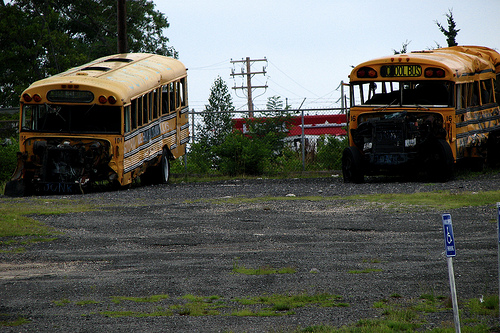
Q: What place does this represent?
A: It represents the road.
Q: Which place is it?
A: It is a road.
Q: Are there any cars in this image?
A: No, there are no cars.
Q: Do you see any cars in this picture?
A: No, there are no cars.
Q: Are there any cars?
A: No, there are no cars.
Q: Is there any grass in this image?
A: Yes, there is grass.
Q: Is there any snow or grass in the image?
A: Yes, there is grass.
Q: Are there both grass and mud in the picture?
A: No, there is grass but no mud.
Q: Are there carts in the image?
A: No, there are no carts.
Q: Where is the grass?
A: The grass is on the road.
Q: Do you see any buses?
A: Yes, there is a bus.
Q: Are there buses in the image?
A: Yes, there is a bus.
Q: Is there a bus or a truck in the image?
A: Yes, there is a bus.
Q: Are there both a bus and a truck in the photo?
A: No, there is a bus but no trucks.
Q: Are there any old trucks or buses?
A: Yes, there is an old bus.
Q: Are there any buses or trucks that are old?
A: Yes, the bus is old.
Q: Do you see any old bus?
A: Yes, there is an old bus.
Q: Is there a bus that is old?
A: Yes, there is a bus that is old.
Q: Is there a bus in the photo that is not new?
A: Yes, there is a old bus.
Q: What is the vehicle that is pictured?
A: The vehicle is a bus.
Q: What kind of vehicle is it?
A: The vehicle is a bus.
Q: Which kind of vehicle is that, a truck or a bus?
A: That is a bus.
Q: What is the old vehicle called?
A: The vehicle is a bus.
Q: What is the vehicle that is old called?
A: The vehicle is a bus.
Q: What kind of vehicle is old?
A: The vehicle is a bus.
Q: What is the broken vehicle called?
A: The vehicle is a bus.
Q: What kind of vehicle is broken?
A: The vehicle is a bus.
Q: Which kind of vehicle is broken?
A: The vehicle is a bus.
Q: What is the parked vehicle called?
A: The vehicle is a bus.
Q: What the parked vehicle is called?
A: The vehicle is a bus.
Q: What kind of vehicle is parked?
A: The vehicle is a bus.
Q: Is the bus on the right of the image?
A: Yes, the bus is on the right of the image.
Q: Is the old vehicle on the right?
A: Yes, the bus is on the right of the image.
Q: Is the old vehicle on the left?
A: No, the bus is on the right of the image.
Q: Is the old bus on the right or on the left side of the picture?
A: The bus is on the right of the image.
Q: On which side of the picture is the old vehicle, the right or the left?
A: The bus is on the right of the image.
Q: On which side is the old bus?
A: The bus is on the right of the image.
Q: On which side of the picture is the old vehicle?
A: The bus is on the right of the image.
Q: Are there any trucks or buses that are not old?
A: No, there is a bus but it is old.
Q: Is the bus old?
A: Yes, the bus is old.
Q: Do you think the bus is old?
A: Yes, the bus is old.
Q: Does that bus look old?
A: Yes, the bus is old.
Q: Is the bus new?
A: No, the bus is old.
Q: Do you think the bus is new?
A: No, the bus is old.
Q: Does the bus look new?
A: No, the bus is old.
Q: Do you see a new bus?
A: No, there is a bus but it is old.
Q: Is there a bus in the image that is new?
A: No, there is a bus but it is old.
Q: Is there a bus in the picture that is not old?
A: No, there is a bus but it is old.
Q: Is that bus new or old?
A: The bus is old.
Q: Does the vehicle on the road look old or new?
A: The bus is old.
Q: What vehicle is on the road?
A: The vehicle is a bus.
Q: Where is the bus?
A: The bus is on the road.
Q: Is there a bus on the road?
A: Yes, there is a bus on the road.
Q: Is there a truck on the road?
A: No, there is a bus on the road.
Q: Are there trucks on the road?
A: No, there is a bus on the road.